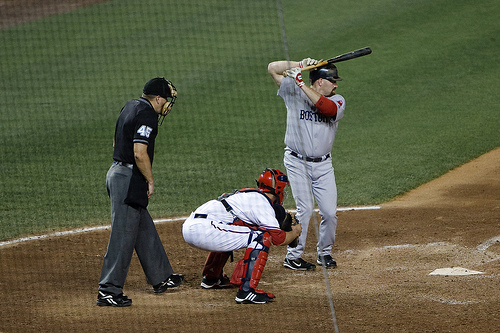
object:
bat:
[300, 46, 372, 71]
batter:
[264, 56, 349, 273]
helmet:
[256, 168, 291, 206]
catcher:
[179, 166, 303, 305]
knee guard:
[248, 231, 275, 290]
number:
[137, 124, 153, 139]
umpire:
[92, 73, 187, 308]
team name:
[299, 109, 331, 124]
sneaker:
[95, 290, 134, 308]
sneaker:
[151, 272, 186, 294]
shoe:
[282, 257, 317, 271]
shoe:
[316, 253, 338, 269]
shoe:
[234, 289, 278, 305]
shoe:
[200, 275, 232, 288]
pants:
[100, 163, 175, 295]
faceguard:
[161, 79, 179, 117]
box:
[228, 240, 272, 287]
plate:
[428, 267, 486, 277]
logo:
[337, 100, 344, 107]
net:
[0, 0, 342, 333]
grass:
[284, 0, 500, 206]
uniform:
[275, 75, 348, 260]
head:
[138, 74, 181, 115]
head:
[308, 61, 343, 96]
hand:
[292, 222, 303, 237]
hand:
[147, 181, 155, 197]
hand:
[282, 66, 303, 86]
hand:
[300, 57, 318, 70]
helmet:
[308, 63, 344, 83]